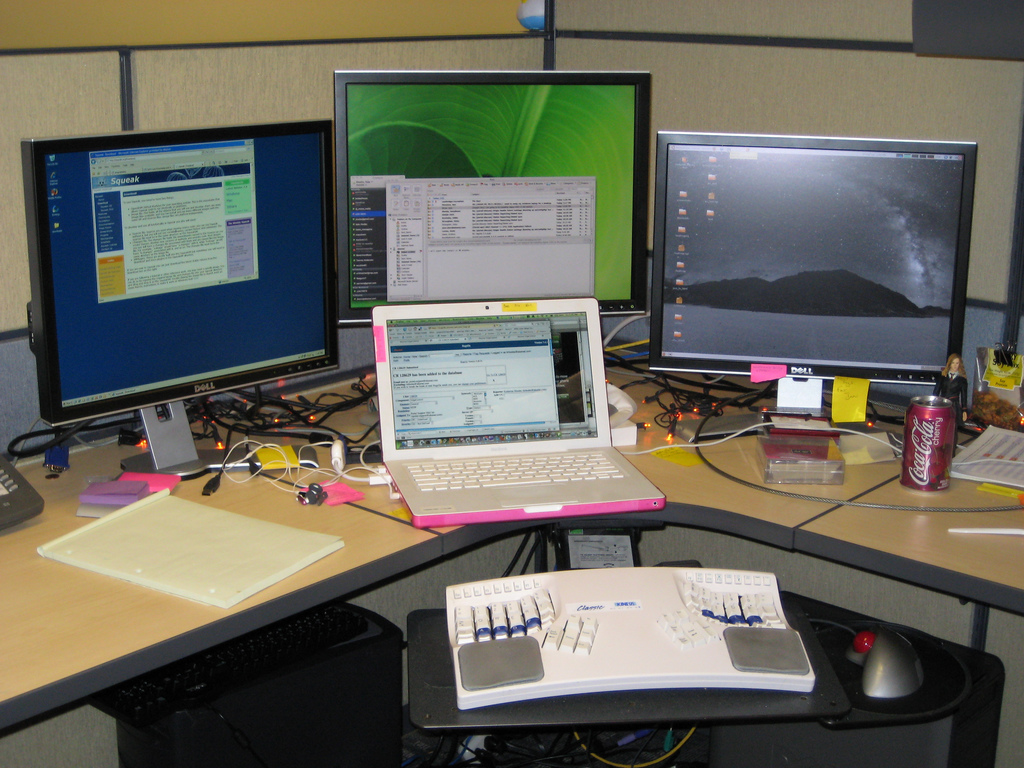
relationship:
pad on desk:
[295, 476, 368, 505] [5, 355, 1023, 728]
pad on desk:
[118, 469, 182, 490] [5, 355, 1023, 728]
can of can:
[901, 395, 956, 491] [901, 395, 956, 497]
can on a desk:
[901, 395, 956, 497] [0, 363, 1022, 678]